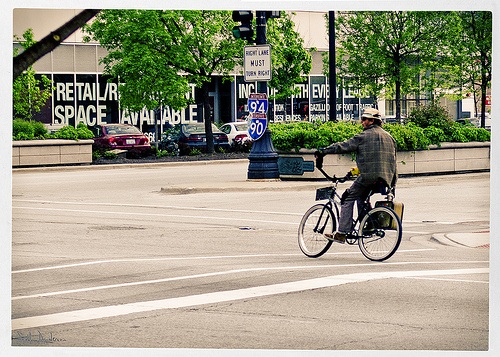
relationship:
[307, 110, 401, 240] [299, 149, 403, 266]
man rides bike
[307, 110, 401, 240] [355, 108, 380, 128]
man has head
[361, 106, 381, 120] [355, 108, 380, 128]
hat on head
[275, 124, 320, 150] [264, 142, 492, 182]
plant on median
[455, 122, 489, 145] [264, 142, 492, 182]
plant on median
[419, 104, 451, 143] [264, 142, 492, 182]
plant on median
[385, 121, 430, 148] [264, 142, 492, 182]
plant on median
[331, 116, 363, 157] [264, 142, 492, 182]
plant on median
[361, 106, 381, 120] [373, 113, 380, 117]
hat has feather